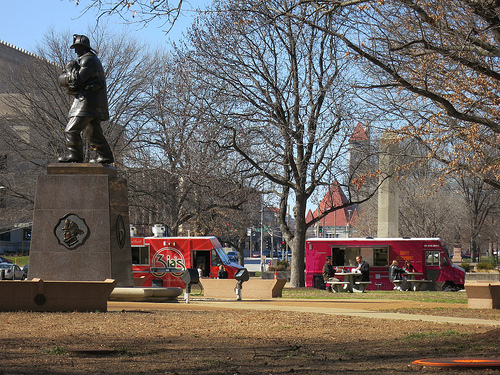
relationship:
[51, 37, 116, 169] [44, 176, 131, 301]
statue has base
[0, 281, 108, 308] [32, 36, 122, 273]
bench next to statue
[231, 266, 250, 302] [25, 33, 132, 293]
light directed at statue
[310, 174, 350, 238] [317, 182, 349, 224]
building has roof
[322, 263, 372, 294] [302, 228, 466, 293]
table next to truck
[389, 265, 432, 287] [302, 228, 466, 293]
table next to truck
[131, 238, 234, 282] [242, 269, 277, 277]
truck parked on street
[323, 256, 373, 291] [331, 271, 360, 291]
people sitting at table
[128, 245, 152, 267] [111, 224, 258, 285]
window of truck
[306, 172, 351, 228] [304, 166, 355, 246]
roof of building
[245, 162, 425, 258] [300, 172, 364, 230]
building with roof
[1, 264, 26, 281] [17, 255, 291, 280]
car parked on road